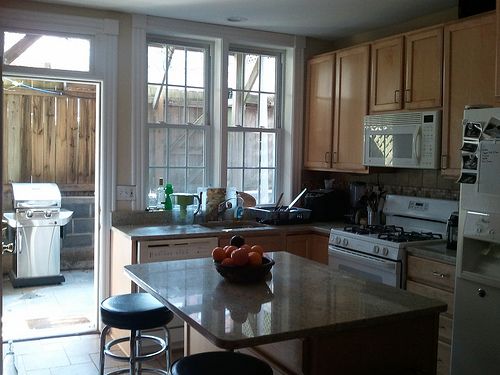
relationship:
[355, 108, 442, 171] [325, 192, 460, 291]
microwave above range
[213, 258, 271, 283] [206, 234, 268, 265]
bowl of fruit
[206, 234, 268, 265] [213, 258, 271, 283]
fruit in a bowl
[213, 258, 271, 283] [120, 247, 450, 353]
bowl on table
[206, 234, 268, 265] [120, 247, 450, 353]
fruit on table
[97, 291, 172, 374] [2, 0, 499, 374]
stool in kitchen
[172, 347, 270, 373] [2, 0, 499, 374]
stool in kitchen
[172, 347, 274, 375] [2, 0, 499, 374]
stool in kitchen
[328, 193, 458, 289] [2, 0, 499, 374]
oven in kitchen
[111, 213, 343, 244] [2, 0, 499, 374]
counter in kitchen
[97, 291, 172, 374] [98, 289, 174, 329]
stool has cushion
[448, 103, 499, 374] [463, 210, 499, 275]
icemaker has icemaker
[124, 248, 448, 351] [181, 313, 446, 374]
counter top on island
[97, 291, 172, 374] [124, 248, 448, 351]
stool at counter top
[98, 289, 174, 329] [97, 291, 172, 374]
cushion of stool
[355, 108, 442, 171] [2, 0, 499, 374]
microwave in kitchen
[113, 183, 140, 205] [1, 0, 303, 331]
switchplate on wall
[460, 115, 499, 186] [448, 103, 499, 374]
pictures on icemaker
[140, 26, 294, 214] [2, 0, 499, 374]
window in kitchen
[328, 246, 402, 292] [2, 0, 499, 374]
oven in kitchen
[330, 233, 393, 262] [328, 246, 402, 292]
knobs on oven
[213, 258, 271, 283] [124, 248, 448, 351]
bowl on counter top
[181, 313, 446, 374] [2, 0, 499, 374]
island in middle of kitchen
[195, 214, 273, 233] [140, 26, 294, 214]
sink by window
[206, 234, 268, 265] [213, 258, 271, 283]
fruit in bowl